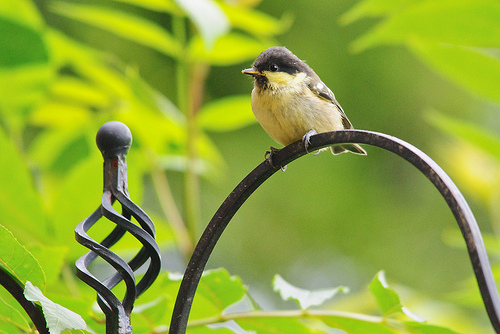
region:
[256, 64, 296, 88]
this is a yellow cheek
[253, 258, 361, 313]
this is a green leaf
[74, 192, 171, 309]
this is woven metal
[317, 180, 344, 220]
this is the color green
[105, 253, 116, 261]
this is the color black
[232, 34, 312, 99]
this is a bird head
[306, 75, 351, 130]
this is a bird wing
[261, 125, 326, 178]
these are bird feet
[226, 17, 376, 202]
this is a bird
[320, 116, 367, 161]
this is a bird tail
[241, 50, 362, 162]
this is a bird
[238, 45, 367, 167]
the bird is small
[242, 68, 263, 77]
this is a beak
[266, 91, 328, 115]
the feathers are white in color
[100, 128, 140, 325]
this is a piece of metal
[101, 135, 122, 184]
the metal is black in color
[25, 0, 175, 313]
these are several plants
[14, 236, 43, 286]
the plant has leaves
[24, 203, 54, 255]
the leaves are green in color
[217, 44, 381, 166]
the bird is perched on the metal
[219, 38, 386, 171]
gray bird with yellow belly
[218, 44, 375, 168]
bird perched on wrought iron type wire structure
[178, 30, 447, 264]
small bird with blurred green background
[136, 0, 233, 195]
plant with long slender stock and long green leaves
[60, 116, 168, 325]
wrought iron with double strand twists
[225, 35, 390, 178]
little bird with grayish black bonnet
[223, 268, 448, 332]
green leafy branch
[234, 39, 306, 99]
finch type bird with black eyes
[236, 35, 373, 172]
yellow breasted finch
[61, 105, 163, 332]
wrought twisted iron with ball shaped top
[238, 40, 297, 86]
the head of a bird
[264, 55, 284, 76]
the eye of a bird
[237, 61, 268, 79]
the beak of a bird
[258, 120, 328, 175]
the feet of a bird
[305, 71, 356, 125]
the wing of a bird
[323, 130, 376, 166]
the tail of a bird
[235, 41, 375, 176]
a bird on the metal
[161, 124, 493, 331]
a black metal arch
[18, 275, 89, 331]
a green leaf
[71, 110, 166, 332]
a black metal pole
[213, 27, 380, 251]
a bird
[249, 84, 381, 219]
a bird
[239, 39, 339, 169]
a bird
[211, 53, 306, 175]
a bird